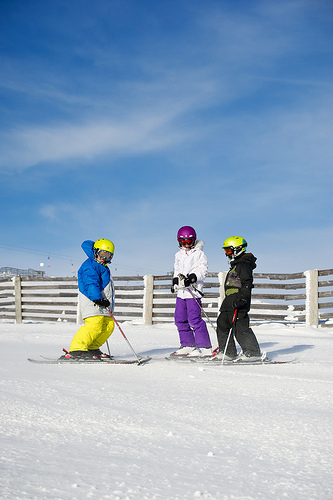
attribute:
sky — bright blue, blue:
[0, 0, 332, 315]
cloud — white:
[0, 93, 207, 172]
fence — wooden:
[0, 267, 332, 327]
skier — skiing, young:
[208, 235, 266, 362]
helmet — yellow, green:
[222, 236, 249, 257]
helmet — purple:
[176, 225, 198, 243]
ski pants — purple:
[173, 297, 211, 348]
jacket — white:
[172, 238, 209, 299]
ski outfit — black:
[216, 252, 262, 360]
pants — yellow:
[68, 315, 115, 352]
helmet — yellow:
[93, 237, 116, 255]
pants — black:
[215, 309, 262, 360]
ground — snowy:
[1, 321, 333, 499]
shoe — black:
[69, 350, 101, 360]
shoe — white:
[188, 347, 213, 358]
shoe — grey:
[236, 353, 263, 363]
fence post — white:
[304, 268, 320, 328]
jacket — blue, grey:
[76, 238, 116, 321]